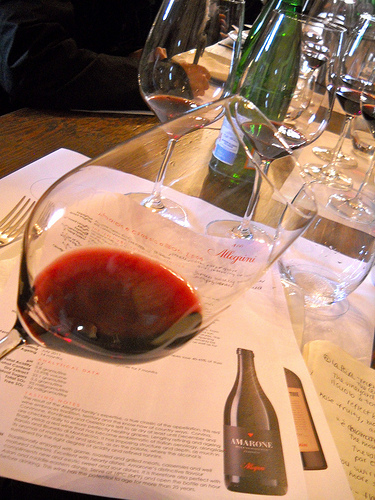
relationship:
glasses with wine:
[0, 96, 320, 359] [20, 245, 204, 360]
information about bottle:
[4, 189, 309, 499] [223, 347, 287, 498]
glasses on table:
[133, 2, 237, 244] [0, 95, 373, 498]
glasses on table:
[221, 10, 347, 249] [0, 95, 373, 498]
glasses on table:
[280, 156, 373, 302] [0, 95, 373, 498]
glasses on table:
[0, 96, 317, 360] [0, 95, 373, 498]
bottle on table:
[209, 0, 306, 193] [0, 107, 362, 214]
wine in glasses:
[20, 245, 204, 360] [0, 96, 320, 359]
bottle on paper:
[223, 347, 287, 498] [149, 320, 296, 455]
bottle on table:
[209, 0, 306, 193] [8, 91, 345, 296]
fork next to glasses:
[1, 197, 50, 248] [0, 96, 320, 359]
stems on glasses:
[146, 132, 184, 215] [120, 6, 374, 261]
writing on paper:
[13, 390, 221, 476] [28, 224, 262, 488]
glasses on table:
[159, 13, 372, 240] [0, 72, 362, 276]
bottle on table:
[206, 0, 307, 196] [7, 19, 371, 488]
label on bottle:
[211, 116, 253, 166] [215, 38, 297, 190]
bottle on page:
[223, 347, 287, 498] [2, 192, 311, 498]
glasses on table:
[268, 181, 375, 322] [7, 19, 371, 488]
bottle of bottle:
[223, 341, 292, 498] [223, 347, 287, 498]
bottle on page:
[223, 341, 292, 498] [2, 192, 311, 498]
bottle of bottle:
[223, 347, 287, 498] [223, 347, 287, 498]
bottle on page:
[209, 0, 306, 193] [2, 192, 311, 498]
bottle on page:
[282, 367, 328, 469] [278, 262, 357, 499]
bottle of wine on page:
[223, 347, 287, 498] [2, 192, 311, 498]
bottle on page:
[282, 367, 330, 473] [269, 257, 349, 499]